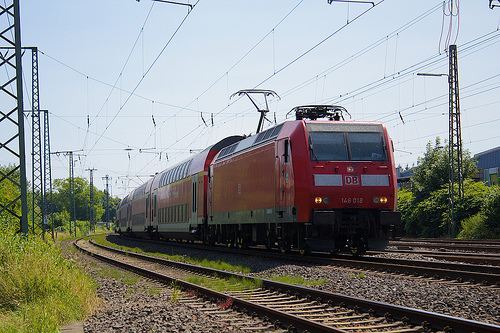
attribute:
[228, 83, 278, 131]
device/train — touching wires on top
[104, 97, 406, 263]
train — red, passenger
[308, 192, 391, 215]
headlights — on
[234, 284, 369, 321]
planks — wood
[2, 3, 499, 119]
wires — electrical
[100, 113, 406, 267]
train — red